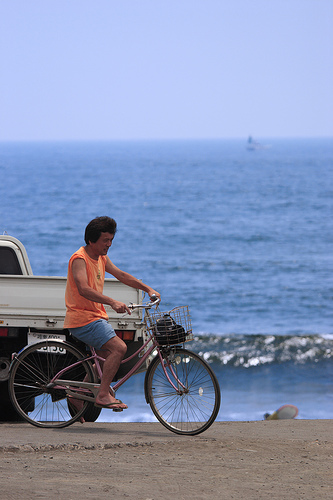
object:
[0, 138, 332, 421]
water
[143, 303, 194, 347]
basket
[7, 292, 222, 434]
bike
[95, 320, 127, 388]
leg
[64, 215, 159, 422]
man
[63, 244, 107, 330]
tank top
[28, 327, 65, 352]
license plate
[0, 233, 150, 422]
truck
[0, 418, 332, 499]
sand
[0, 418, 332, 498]
beach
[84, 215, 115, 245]
hair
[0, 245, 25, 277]
window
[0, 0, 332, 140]
clouds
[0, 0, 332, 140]
sky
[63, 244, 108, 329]
shirt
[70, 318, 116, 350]
shorts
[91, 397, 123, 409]
sandals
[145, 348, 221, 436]
wheel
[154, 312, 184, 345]
bag